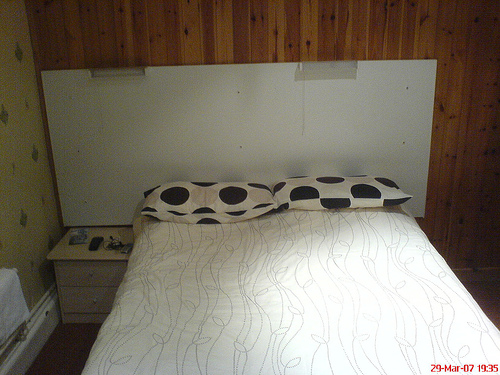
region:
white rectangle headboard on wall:
[28, 47, 443, 239]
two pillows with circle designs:
[137, 165, 414, 230]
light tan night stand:
[44, 209, 144, 331]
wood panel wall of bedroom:
[419, 105, 489, 249]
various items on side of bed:
[71, 228, 134, 255]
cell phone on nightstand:
[82, 229, 109, 259]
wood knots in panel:
[241, 9, 328, 54]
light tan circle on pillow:
[182, 185, 219, 215]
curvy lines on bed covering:
[159, 250, 273, 352]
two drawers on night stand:
[52, 263, 113, 325]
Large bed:
[97, 218, 491, 374]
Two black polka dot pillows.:
[149, 171, 415, 222]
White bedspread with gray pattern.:
[140, 220, 461, 369]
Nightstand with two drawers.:
[42, 217, 134, 338]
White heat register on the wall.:
[0, 285, 50, 366]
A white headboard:
[48, 54, 434, 212]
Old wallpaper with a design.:
[1, 95, 58, 283]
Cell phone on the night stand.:
[81, 234, 106, 252]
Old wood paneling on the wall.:
[38, 2, 498, 45]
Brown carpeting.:
[60, 320, 94, 373]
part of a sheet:
[242, 263, 307, 320]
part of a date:
[453, 359, 481, 371]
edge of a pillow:
[232, 202, 264, 227]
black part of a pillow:
[225, 184, 242, 202]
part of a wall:
[117, 120, 151, 145]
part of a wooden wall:
[449, 157, 486, 239]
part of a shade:
[311, 60, 371, 95]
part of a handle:
[78, 261, 104, 288]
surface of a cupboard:
[56, 228, 98, 260]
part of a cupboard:
[58, 262, 97, 304]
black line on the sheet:
[164, 311, 208, 350]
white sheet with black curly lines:
[142, 266, 324, 372]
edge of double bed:
[100, 293, 147, 344]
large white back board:
[136, 95, 420, 160]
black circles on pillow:
[283, 182, 331, 211]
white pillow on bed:
[129, 167, 302, 244]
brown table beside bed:
[38, 236, 141, 322]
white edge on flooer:
[20, 300, 64, 341]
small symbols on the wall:
[18, 140, 56, 224]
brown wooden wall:
[437, 118, 499, 225]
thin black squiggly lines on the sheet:
[73, 208, 492, 370]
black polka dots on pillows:
[137, 154, 415, 231]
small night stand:
[48, 221, 142, 327]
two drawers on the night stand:
[53, 261, 135, 324]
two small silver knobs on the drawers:
[79, 267, 102, 308]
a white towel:
[0, 263, 35, 340]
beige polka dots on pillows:
[132, 171, 417, 226]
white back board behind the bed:
[46, 39, 442, 234]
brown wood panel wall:
[24, 0, 494, 268]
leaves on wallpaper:
[0, 1, 91, 321]